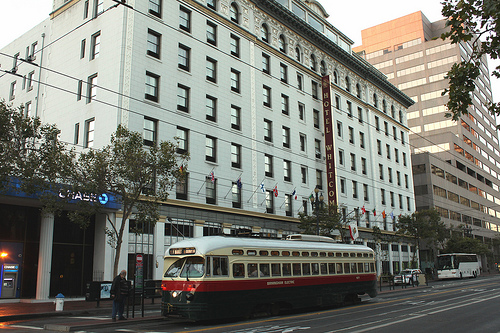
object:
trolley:
[160, 232, 380, 324]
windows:
[233, 262, 245, 278]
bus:
[434, 252, 484, 280]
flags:
[223, 172, 243, 200]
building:
[0, 0, 418, 305]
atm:
[0, 262, 20, 299]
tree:
[87, 146, 153, 209]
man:
[110, 269, 131, 322]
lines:
[391, 294, 431, 310]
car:
[392, 268, 422, 286]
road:
[392, 286, 499, 326]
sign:
[321, 72, 341, 215]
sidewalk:
[5, 293, 142, 323]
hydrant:
[52, 292, 65, 312]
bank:
[1, 172, 124, 304]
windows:
[176, 83, 189, 113]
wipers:
[186, 263, 192, 282]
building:
[347, 10, 499, 279]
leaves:
[114, 130, 169, 180]